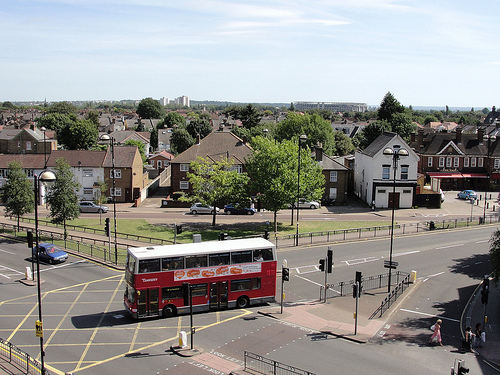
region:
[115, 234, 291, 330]
A double decker bus.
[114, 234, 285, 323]
The bus is red and white.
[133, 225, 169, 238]
The grass is green.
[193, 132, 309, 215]
The trees are green.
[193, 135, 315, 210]
The trees have leaves on them.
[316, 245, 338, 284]
A traffic light.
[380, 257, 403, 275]
A street sign.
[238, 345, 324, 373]
A metal fence.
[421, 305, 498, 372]
People are walking in the picture.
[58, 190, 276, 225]
Cars are in the background.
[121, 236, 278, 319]
a red and white double decker bus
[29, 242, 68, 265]
a blue car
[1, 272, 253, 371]
crossed yellow lines marking the intersection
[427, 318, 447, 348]
a woman in pink crossing the street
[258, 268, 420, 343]
a triangular patch of concrete in the intersection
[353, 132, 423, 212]
a two story white house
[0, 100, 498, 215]
a bunch of houses in the background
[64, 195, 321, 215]
a row of cars parked on the street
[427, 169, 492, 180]
a red awning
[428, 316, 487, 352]
people crossing the street on foot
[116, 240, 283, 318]
red double decker bus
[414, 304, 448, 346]
woman walking across road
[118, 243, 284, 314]
bus driving through intersection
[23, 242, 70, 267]
blue car waiting to cross intersection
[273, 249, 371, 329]
traffic lights in center of intersection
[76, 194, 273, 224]
cars parked on street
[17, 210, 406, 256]
green space between roads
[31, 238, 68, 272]
blue car on road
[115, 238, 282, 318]
red and white bus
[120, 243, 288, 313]
red and white double decker bus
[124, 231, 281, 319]
a double decker bus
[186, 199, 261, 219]
two parked cars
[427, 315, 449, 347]
woman crossing a road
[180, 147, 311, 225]
a grouping of trees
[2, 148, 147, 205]
a row of houses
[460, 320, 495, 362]
people walking on the sidewalk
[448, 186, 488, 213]
a car in a parking lot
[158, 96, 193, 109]
two skyscrapers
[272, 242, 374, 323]
three sets of traffic signals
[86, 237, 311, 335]
double decker red and white bus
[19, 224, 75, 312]
blue car waiting at red light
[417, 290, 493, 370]
3 people crossing the street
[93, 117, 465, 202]
several houses in a neighborhood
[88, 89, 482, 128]
skyline with trees, buildings, and houses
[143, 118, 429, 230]
neighborhood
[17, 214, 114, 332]
blue car waiting at red light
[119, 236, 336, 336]
red double decker bus going through intersection